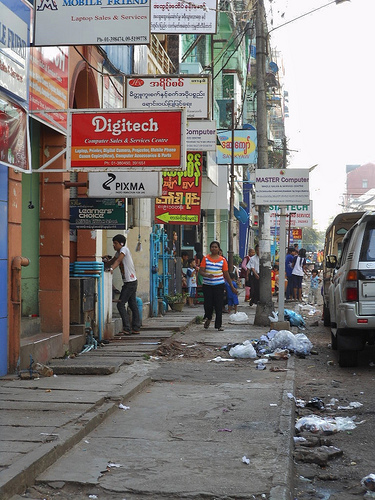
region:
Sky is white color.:
[309, 26, 364, 133]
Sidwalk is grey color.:
[75, 361, 256, 484]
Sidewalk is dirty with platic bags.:
[208, 292, 352, 459]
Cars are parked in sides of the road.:
[313, 215, 373, 381]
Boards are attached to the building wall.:
[15, 0, 230, 210]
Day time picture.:
[8, 10, 353, 481]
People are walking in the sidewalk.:
[165, 222, 296, 327]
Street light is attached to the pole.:
[259, 1, 355, 46]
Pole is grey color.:
[251, 1, 273, 323]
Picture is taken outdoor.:
[11, 9, 362, 476]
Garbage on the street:
[219, 292, 321, 369]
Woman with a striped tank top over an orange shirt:
[196, 239, 233, 332]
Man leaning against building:
[104, 231, 141, 333]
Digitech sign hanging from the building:
[64, 106, 184, 173]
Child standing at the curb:
[307, 264, 320, 306]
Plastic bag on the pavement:
[225, 310, 248, 325]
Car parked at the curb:
[324, 213, 373, 371]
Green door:
[16, 145, 42, 319]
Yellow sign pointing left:
[155, 211, 199, 223]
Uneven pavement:
[0, 303, 208, 466]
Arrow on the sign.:
[150, 209, 204, 227]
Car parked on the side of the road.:
[315, 202, 373, 374]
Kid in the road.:
[300, 263, 325, 306]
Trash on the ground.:
[224, 303, 318, 371]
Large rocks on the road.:
[289, 424, 346, 469]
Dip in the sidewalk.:
[64, 374, 293, 498]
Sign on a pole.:
[251, 166, 314, 332]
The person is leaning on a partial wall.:
[98, 232, 151, 332]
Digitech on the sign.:
[84, 112, 163, 138]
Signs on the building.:
[1, 1, 325, 255]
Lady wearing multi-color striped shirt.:
[193, 240, 240, 334]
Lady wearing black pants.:
[197, 240, 239, 331]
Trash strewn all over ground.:
[7, 243, 372, 499]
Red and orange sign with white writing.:
[62, 105, 193, 175]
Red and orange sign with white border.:
[66, 103, 188, 176]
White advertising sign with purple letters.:
[252, 167, 313, 205]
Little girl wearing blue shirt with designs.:
[308, 267, 322, 305]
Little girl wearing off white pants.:
[302, 264, 323, 306]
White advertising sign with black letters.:
[84, 169, 165, 201]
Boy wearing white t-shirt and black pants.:
[105, 231, 143, 336]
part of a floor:
[193, 439, 247, 478]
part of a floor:
[159, 407, 211, 473]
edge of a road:
[282, 452, 301, 475]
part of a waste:
[297, 429, 324, 479]